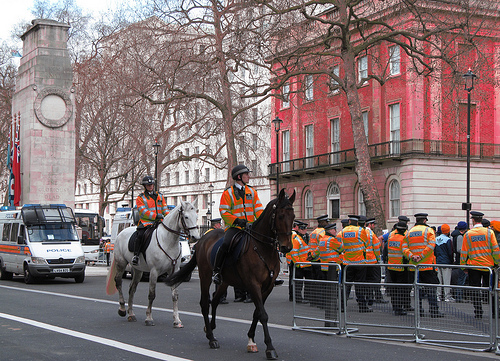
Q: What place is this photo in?
A: It is at the city.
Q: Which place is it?
A: It is a city.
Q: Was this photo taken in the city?
A: Yes, it was taken in the city.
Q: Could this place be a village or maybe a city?
A: It is a city.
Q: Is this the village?
A: No, it is the city.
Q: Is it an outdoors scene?
A: Yes, it is outdoors.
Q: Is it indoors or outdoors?
A: It is outdoors.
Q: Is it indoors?
A: No, it is outdoors.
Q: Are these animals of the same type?
A: Yes, all the animals are horses.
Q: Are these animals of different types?
A: No, all the animals are horses.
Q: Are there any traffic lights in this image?
A: No, there are no traffic lights.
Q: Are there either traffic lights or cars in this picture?
A: No, there are no traffic lights or cars.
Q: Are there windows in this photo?
A: Yes, there is a window.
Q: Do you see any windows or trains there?
A: Yes, there is a window.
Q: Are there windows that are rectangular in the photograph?
A: Yes, there is a rectangular window.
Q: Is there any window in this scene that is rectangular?
A: Yes, there is a window that is rectangular.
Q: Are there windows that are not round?
A: Yes, there is a rectangular window.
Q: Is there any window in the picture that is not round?
A: Yes, there is a rectangular window.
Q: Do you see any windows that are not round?
A: Yes, there is a rectangular window.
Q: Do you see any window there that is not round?
A: Yes, there is a rectangular window.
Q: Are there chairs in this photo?
A: No, there are no chairs.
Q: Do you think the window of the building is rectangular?
A: Yes, the window is rectangular.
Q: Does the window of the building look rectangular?
A: Yes, the window is rectangular.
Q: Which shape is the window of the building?
A: The window is rectangular.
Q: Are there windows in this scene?
A: Yes, there is a window.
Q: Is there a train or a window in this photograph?
A: Yes, there is a window.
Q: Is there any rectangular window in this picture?
A: Yes, there is a rectangular window.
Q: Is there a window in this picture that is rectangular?
A: Yes, there is a window that is rectangular.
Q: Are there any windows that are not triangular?
A: Yes, there is a rectangular window.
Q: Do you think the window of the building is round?
A: No, the window is rectangular.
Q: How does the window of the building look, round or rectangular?
A: The window is rectangular.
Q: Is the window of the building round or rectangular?
A: The window is rectangular.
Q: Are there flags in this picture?
A: Yes, there is a flag.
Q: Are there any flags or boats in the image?
A: Yes, there is a flag.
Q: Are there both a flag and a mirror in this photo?
A: No, there is a flag but no mirrors.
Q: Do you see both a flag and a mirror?
A: No, there is a flag but no mirrors.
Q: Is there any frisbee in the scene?
A: No, there are no frisbees.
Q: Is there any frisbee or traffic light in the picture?
A: No, there are no frisbees or traffic lights.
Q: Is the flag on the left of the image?
A: Yes, the flag is on the left of the image.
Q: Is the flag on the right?
A: No, the flag is on the left of the image.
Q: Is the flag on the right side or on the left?
A: The flag is on the left of the image.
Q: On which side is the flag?
A: The flag is on the left of the image.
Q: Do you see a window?
A: Yes, there is a window.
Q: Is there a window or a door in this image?
A: Yes, there is a window.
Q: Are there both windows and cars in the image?
A: No, there is a window but no cars.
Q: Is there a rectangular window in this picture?
A: Yes, there is a rectangular window.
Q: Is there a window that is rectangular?
A: Yes, there is a window that is rectangular.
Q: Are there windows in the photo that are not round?
A: Yes, there is a rectangular window.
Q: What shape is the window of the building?
A: The window is rectangular.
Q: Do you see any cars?
A: No, there are no cars.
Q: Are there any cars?
A: No, there are no cars.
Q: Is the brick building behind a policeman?
A: Yes, the building is behind a policeman.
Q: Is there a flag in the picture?
A: Yes, there is a flag.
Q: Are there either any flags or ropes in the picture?
A: Yes, there is a flag.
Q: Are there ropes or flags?
A: Yes, there is a flag.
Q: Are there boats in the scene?
A: No, there are no boats.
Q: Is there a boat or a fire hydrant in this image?
A: No, there are no boats or fire hydrants.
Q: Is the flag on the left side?
A: Yes, the flag is on the left of the image.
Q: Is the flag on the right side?
A: No, the flag is on the left of the image.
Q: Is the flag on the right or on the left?
A: The flag is on the left of the image.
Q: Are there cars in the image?
A: No, there are no cars.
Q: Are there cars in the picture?
A: No, there are no cars.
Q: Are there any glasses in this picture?
A: No, there are no glasses.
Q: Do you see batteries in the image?
A: No, there are no batteries.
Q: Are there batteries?
A: No, there are no batteries.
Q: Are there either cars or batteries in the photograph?
A: No, there are no batteries or cars.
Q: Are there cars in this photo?
A: No, there are no cars.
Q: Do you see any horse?
A: Yes, there is a horse.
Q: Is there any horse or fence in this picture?
A: Yes, there is a horse.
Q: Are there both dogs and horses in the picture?
A: No, there is a horse but no dogs.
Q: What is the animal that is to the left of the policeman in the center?
A: The animal is a horse.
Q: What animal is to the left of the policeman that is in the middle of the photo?
A: The animal is a horse.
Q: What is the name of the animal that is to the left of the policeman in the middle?
A: The animal is a horse.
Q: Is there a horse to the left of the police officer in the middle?
A: Yes, there is a horse to the left of the policeman.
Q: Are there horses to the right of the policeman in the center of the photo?
A: No, the horse is to the left of the policeman.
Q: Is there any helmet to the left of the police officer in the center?
A: No, there is a horse to the left of the police officer.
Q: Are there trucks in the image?
A: No, there are no trucks.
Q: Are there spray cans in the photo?
A: No, there are no spray cans.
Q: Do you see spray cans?
A: No, there are no spray cans.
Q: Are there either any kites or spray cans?
A: No, there are no spray cans or kites.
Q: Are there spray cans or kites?
A: No, there are no spray cans or kites.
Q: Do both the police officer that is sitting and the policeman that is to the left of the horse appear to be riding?
A: Yes, both the police officer and the policeman are riding.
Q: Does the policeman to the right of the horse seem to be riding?
A: Yes, the police officer is riding.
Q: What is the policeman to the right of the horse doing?
A: The policeman is riding.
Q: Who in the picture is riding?
A: The police officer is riding.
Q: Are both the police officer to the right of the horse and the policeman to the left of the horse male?
A: Yes, both the policeman and the policeman are male.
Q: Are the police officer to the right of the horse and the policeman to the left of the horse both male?
A: Yes, both the policeman and the policeman are male.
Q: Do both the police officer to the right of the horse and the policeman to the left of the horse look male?
A: Yes, both the policeman and the policeman are male.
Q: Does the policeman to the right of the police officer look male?
A: Yes, the police officer is male.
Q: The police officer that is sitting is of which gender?
A: The police officer is male.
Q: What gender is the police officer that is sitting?
A: The police officer is male.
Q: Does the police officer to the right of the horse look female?
A: No, the policeman is male.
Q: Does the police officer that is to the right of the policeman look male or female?
A: The policeman is male.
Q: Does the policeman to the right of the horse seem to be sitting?
A: Yes, the policeman is sitting.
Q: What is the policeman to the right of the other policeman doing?
A: The police officer is sitting.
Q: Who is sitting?
A: The police officer is sitting.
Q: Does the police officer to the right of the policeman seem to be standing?
A: No, the police officer is sitting.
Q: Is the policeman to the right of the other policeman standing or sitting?
A: The policeman is sitting.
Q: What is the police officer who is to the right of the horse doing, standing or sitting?
A: The policeman is sitting.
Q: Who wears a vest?
A: The police officer wears a vest.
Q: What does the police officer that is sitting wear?
A: The police officer wears a vest.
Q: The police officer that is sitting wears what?
A: The police officer wears a vest.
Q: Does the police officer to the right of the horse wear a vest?
A: Yes, the police officer wears a vest.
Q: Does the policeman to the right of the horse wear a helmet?
A: No, the police officer wears a vest.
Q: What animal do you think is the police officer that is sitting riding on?
A: The policeman is riding on a horse.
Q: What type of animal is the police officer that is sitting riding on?
A: The police officer is riding on a horse.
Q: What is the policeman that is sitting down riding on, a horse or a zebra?
A: The policeman is riding on a horse.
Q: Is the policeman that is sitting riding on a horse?
A: Yes, the policeman is riding on a horse.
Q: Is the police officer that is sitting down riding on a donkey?
A: No, the policeman is riding on a horse.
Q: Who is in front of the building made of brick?
A: The policeman is in front of the building.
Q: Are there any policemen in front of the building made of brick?
A: Yes, there is a policeman in front of the building.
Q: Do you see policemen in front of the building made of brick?
A: Yes, there is a policeman in front of the building.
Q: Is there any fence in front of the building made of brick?
A: No, there is a policeman in front of the building.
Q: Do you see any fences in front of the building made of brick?
A: No, there is a policeman in front of the building.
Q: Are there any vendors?
A: No, there are no vendors.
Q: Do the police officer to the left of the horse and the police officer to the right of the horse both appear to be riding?
A: Yes, both the policeman and the police officer are riding.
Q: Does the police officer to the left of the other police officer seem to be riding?
A: Yes, the policeman is riding.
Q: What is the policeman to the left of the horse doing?
A: The police officer is riding.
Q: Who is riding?
A: The police officer is riding.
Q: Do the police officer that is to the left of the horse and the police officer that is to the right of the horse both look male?
A: Yes, both the policeman and the policeman are male.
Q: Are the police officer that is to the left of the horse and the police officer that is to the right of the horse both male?
A: Yes, both the policeman and the policeman are male.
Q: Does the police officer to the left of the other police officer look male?
A: Yes, the policeman is male.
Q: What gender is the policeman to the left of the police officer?
A: The police officer is male.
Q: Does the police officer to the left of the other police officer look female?
A: No, the policeman is male.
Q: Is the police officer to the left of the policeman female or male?
A: The policeman is male.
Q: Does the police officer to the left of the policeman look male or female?
A: The policeman is male.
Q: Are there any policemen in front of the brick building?
A: Yes, there is a policeman in front of the building.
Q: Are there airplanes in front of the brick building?
A: No, there is a policeman in front of the building.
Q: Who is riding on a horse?
A: The police officer is riding on a horse.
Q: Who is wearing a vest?
A: The police officer is wearing a vest.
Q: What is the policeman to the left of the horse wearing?
A: The police officer is wearing a vest.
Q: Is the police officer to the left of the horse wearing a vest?
A: Yes, the policeman is wearing a vest.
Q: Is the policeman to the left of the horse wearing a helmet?
A: No, the police officer is wearing a vest.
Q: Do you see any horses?
A: Yes, there is a horse.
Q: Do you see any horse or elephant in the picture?
A: Yes, there is a horse.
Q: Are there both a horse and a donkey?
A: No, there is a horse but no donkeys.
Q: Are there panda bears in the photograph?
A: No, there are no panda bears.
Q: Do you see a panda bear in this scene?
A: No, there are no panda bears.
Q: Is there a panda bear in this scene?
A: No, there are no panda bears.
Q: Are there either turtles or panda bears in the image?
A: No, there are no panda bears or turtles.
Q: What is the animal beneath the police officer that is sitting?
A: The animal is a horse.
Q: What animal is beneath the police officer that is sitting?
A: The animal is a horse.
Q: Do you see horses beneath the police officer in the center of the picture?
A: Yes, there is a horse beneath the policeman.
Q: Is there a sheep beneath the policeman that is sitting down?
A: No, there is a horse beneath the police officer.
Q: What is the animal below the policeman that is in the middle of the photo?
A: The animal is a horse.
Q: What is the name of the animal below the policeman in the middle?
A: The animal is a horse.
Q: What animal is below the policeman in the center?
A: The animal is a horse.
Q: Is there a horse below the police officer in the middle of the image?
A: Yes, there is a horse below the policeman.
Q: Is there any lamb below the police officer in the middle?
A: No, there is a horse below the police officer.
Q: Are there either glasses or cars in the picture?
A: No, there are no cars or glasses.